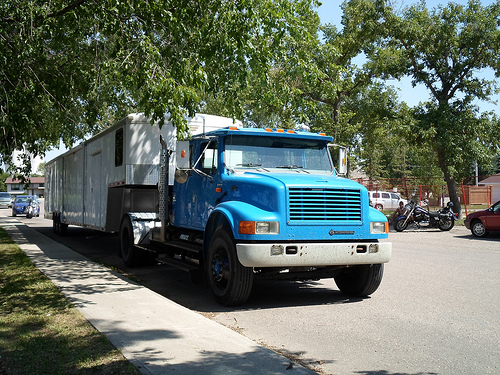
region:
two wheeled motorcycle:
[389, 192, 456, 234]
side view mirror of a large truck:
[174, 142, 192, 171]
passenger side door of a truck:
[179, 145, 209, 231]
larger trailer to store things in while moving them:
[41, 125, 151, 225]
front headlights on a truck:
[240, 220, 284, 234]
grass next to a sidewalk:
[1, 270, 83, 374]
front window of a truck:
[227, 140, 329, 167]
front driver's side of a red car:
[458, 201, 498, 246]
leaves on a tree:
[5, 3, 294, 90]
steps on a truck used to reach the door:
[142, 234, 209, 271]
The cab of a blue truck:
[179, 133, 391, 307]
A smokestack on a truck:
[150, 135, 180, 246]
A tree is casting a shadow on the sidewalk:
[57, 267, 144, 322]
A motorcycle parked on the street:
[389, 192, 461, 232]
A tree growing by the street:
[367, 0, 490, 211]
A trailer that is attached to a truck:
[45, 111, 165, 264]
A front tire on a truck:
[202, 232, 250, 309]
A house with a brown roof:
[5, 172, 48, 195]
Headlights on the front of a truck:
[235, 218, 398, 246]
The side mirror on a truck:
[337, 141, 352, 179]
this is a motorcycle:
[392, 193, 484, 248]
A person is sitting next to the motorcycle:
[376, 177, 469, 261]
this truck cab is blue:
[152, 112, 431, 297]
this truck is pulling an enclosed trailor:
[34, 139, 461, 322]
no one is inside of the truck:
[169, 111, 409, 295]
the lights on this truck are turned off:
[165, 116, 441, 317]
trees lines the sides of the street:
[4, 111, 498, 267]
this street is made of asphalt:
[113, 211, 450, 373]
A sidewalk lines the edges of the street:
[0, 186, 132, 373]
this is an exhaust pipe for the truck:
[147, 122, 194, 269]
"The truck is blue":
[115, 137, 434, 312]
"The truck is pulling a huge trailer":
[13, 109, 420, 324]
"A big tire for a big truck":
[194, 213, 273, 315]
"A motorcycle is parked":
[377, 182, 464, 242]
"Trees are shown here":
[338, 68, 498, 195]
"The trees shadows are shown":
[3, 194, 341, 370]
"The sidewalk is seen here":
[0, 195, 281, 372]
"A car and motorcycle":
[6, 181, 57, 229]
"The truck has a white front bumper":
[213, 121, 404, 278]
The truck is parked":
[30, 91, 437, 328]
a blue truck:
[26, 82, 427, 324]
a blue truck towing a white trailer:
[22, 88, 394, 318]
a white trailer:
[31, 90, 233, 288]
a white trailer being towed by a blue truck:
[48, 115, 402, 308]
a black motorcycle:
[378, 175, 468, 235]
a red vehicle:
[455, 175, 496, 245]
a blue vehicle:
[5, 187, 44, 230]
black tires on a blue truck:
[103, 187, 440, 328]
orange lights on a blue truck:
[227, 197, 465, 249]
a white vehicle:
[340, 165, 425, 232]